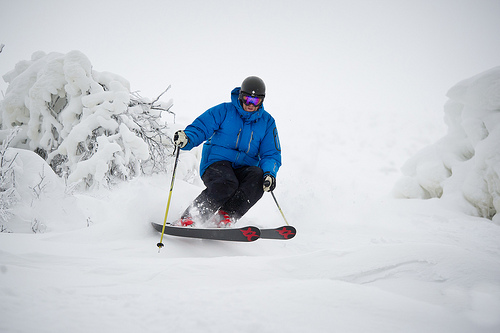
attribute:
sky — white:
[284, 44, 330, 75]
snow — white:
[63, 74, 131, 142]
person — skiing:
[188, 114, 284, 215]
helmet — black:
[231, 35, 340, 149]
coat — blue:
[197, 112, 265, 155]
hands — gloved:
[116, 137, 291, 171]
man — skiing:
[115, 95, 370, 229]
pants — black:
[194, 153, 371, 289]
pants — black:
[183, 182, 270, 232]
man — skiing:
[189, 148, 242, 177]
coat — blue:
[188, 90, 270, 178]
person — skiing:
[194, 120, 313, 250]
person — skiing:
[159, 109, 353, 264]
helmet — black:
[215, 60, 291, 114]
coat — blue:
[182, 85, 284, 180]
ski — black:
[148, 221, 264, 241]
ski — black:
[254, 224, 296, 239]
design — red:
[240, 224, 259, 237]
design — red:
[276, 221, 294, 239]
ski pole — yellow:
[156, 140, 183, 250]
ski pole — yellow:
[265, 185, 289, 225]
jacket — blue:
[179, 87, 284, 175]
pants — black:
[192, 158, 264, 218]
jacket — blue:
[182, 81, 284, 180]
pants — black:
[197, 160, 270, 220]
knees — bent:
[208, 164, 269, 201]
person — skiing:
[149, 70, 293, 268]